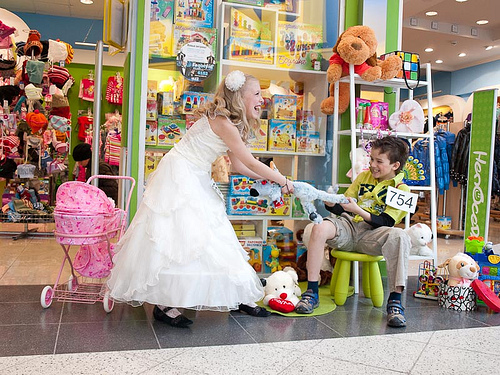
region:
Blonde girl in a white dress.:
[105, 70, 292, 329]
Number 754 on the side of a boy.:
[385, 184, 415, 214]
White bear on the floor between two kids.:
[257, 268, 302, 316]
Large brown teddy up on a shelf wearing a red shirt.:
[321, 20, 403, 115]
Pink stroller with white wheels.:
[38, 174, 138, 310]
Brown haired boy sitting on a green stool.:
[292, 135, 413, 329]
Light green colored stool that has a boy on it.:
[325, 247, 388, 305]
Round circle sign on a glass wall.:
[175, 42, 216, 81]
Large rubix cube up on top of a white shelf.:
[380, 51, 421, 84]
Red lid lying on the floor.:
[470, 278, 498, 313]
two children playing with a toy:
[141, 62, 413, 304]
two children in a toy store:
[0, 16, 497, 288]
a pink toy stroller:
[35, 174, 135, 325]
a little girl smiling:
[208, 64, 272, 172]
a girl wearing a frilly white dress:
[116, 71, 261, 331]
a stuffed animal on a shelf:
[310, 20, 405, 125]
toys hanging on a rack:
[1, 27, 81, 201]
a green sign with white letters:
[464, 84, 486, 275]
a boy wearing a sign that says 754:
[349, 128, 421, 265]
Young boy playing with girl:
[296, 137, 426, 327]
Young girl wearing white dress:
[106, 67, 291, 327]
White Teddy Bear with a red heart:
[257, 265, 299, 315]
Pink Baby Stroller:
[35, 170, 131, 310]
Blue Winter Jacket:
[401, 135, 441, 190]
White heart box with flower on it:
[385, 95, 422, 135]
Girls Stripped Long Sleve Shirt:
[101, 130, 121, 165]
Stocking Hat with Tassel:
[21, 25, 41, 55]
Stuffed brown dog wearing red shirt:
[320, 24, 402, 116]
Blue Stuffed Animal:
[248, 153, 355, 219]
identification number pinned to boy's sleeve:
[385, 185, 416, 212]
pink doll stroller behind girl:
[33, 168, 135, 318]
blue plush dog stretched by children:
[250, 166, 357, 233]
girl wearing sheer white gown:
[99, 67, 298, 335]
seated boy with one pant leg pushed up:
[298, 132, 412, 332]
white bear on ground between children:
[262, 260, 299, 320]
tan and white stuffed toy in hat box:
[436, 248, 498, 322]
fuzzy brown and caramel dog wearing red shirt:
[320, 25, 402, 117]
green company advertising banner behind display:
[465, 85, 492, 249]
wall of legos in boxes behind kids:
[147, 0, 334, 271]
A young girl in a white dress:
[84, 58, 310, 343]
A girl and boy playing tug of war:
[145, 58, 412, 347]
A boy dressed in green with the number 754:
[288, 136, 425, 342]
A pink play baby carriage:
[28, 162, 145, 321]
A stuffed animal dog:
[311, 25, 394, 122]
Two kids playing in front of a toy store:
[0, 23, 479, 360]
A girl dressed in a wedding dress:
[104, 46, 296, 332]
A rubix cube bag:
[367, 47, 432, 92]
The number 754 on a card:
[384, 185, 419, 220]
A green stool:
[328, 244, 385, 311]